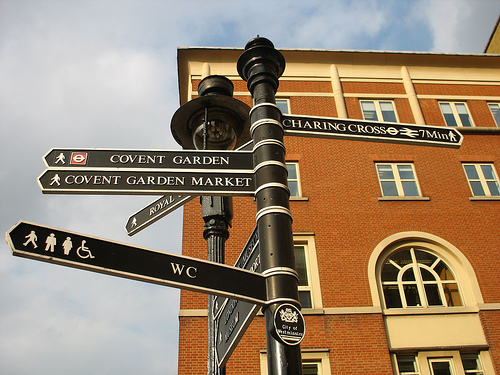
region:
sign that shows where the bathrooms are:
[5, 218, 265, 306]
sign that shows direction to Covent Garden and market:
[34, 145, 258, 193]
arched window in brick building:
[366, 229, 487, 309]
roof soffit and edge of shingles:
[175, 43, 499, 65]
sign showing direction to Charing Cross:
[279, 111, 463, 143]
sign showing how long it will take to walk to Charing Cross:
[275, 114, 466, 146]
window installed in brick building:
[372, 155, 432, 205]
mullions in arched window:
[378, 238, 471, 309]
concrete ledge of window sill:
[376, 193, 433, 204]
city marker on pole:
[272, 300, 307, 345]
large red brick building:
[173, 35, 498, 366]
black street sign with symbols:
[5, 211, 265, 322]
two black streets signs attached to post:
[35, 136, 260, 196]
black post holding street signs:
[231, 32, 316, 368]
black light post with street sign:
[200, 95, 225, 370]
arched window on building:
[365, 221, 477, 316]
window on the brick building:
[370, 146, 426, 203]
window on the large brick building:
[455, 155, 495, 210]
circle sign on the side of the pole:
[275, 291, 296, 346]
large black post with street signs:
[7, 42, 469, 372]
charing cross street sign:
[284, 115, 462, 151]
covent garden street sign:
[31, 147, 252, 172]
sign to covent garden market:
[39, 163, 254, 195]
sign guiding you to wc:
[12, 220, 270, 317]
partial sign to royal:
[121, 198, 188, 234]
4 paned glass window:
[376, 163, 424, 198]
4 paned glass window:
[461, 158, 498, 200]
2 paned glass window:
[438, 100, 477, 129]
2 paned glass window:
[360, 100, 398, 125]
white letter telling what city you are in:
[271, 300, 304, 353]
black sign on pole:
[278, 114, 462, 136]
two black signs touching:
[35, 139, 272, 199]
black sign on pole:
[0, 221, 272, 308]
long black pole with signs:
[254, 24, 293, 374]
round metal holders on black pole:
[231, 100, 307, 297]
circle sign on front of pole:
[270, 291, 303, 354]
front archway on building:
[348, 225, 477, 321]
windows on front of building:
[338, 73, 480, 205]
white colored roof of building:
[265, 43, 492, 75]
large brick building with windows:
[166, 45, 498, 374]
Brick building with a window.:
[369, 149, 427, 206]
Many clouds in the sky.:
[62, 35, 157, 104]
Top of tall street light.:
[167, 62, 247, 147]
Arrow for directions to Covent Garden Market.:
[37, 170, 252, 197]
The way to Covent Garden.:
[39, 145, 254, 167]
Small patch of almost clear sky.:
[363, 16, 439, 51]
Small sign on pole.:
[265, 293, 315, 352]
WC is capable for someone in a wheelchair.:
[2, 215, 106, 271]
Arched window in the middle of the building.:
[357, 216, 484, 311]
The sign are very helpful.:
[8, 131, 257, 302]